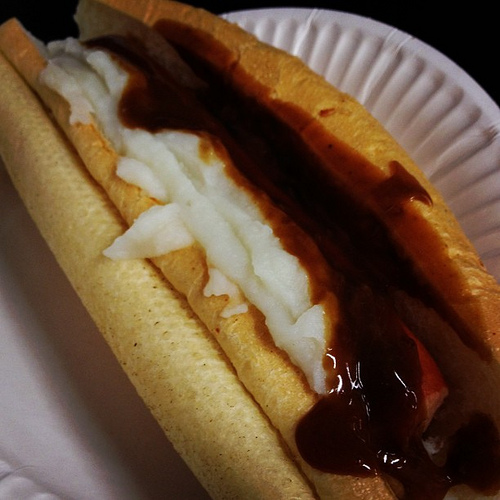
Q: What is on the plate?
A: Hot dog.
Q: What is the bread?
A: Bun.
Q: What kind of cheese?
A: Melted.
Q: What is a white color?
A: Paper plate.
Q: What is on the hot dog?
A: Brown sauce.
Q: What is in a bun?
A: A hot dog.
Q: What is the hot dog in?
A: A bun.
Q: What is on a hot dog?
A: BBQ sauce.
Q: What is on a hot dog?
A: Onions.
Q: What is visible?
A: A hot dog.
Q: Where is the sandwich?
A: On a paper plate.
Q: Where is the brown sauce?
A: In the sandwich.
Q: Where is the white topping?
A: In the sandwich?.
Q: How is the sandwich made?
A: With a hot dog.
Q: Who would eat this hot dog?
A: An experimenter.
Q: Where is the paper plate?
A: Under the hot dog.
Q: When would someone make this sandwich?
A: When there are mashed potatoes and gravy leftovers.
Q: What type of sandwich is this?
A: A meat and potatoes sandwich.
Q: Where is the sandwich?
A: On a table.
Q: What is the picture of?
A: The hot dog.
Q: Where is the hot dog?
A: Bun.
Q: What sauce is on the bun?
A: Barbque.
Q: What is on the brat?
A: Potatoes and gravy.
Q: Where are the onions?
A: On hot dog.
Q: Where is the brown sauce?
A: On the hot dog.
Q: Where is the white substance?
A: On the hotdog.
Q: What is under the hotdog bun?
A: Papper plate.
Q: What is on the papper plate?
A: Hotdog.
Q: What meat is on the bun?
A: A hot dog.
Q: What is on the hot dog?
A: Mashed potatoes and gravy.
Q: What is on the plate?
A: The food.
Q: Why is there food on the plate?
A: So it can be eaten.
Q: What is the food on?
A: A plate.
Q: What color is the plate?
A: White.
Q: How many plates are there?
A: One.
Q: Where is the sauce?
A: On the food.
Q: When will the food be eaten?
A: Now.